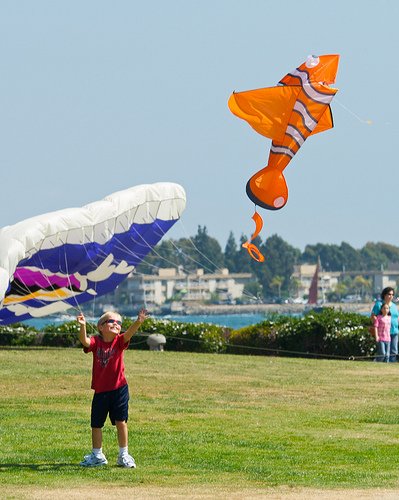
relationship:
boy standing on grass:
[76, 307, 151, 468] [0, 345, 398, 500]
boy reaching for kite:
[76, 307, 151, 468] [227, 53, 341, 262]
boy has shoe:
[76, 307, 151, 468] [78, 452, 109, 468]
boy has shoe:
[76, 307, 151, 468] [116, 452, 137, 469]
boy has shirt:
[76, 307, 151, 468] [83, 332, 130, 394]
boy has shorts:
[76, 307, 151, 468] [90, 384, 129, 428]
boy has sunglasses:
[76, 307, 151, 468] [100, 318, 123, 326]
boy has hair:
[76, 307, 151, 468] [97, 311, 122, 336]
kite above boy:
[227, 53, 341, 262] [76, 307, 151, 468]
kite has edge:
[0, 181, 187, 326] [0, 181, 187, 310]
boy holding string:
[76, 307, 151, 468] [57, 231, 101, 336]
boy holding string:
[76, 307, 151, 468] [85, 229, 261, 302]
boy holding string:
[76, 307, 151, 468] [119, 213, 259, 301]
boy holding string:
[76, 307, 151, 468] [142, 210, 259, 300]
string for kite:
[57, 231, 101, 336] [0, 181, 187, 326]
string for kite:
[85, 229, 261, 302] [0, 181, 187, 326]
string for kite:
[119, 213, 259, 301] [0, 181, 187, 326]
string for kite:
[142, 210, 259, 300] [0, 181, 187, 326]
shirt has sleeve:
[83, 332, 130, 394] [118, 332, 131, 350]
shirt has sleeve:
[83, 332, 130, 394] [83, 336, 96, 354]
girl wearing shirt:
[372, 302, 392, 362] [373, 314, 392, 342]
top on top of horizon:
[223, 231, 239, 275] [31, 223, 398, 319]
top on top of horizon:
[341, 241, 363, 270] [31, 223, 398, 319]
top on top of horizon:
[236, 232, 251, 273] [31, 223, 398, 319]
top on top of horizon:
[135, 239, 180, 273] [31, 223, 398, 319]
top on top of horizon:
[168, 236, 201, 268] [31, 223, 398, 319]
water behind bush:
[20, 311, 371, 330] [1, 322, 39, 347]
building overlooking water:
[85, 264, 251, 310] [20, 311, 371, 330]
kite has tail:
[227, 53, 341, 262] [241, 166, 289, 263]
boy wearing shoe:
[76, 307, 151, 468] [78, 452, 109, 468]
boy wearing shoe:
[76, 307, 151, 468] [116, 452, 137, 469]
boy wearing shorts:
[76, 307, 151, 468] [90, 384, 129, 428]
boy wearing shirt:
[76, 307, 151, 468] [83, 332, 130, 394]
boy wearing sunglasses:
[76, 307, 151, 468] [100, 318, 123, 326]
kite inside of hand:
[0, 181, 187, 326] [76, 312, 86, 326]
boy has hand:
[76, 307, 151, 468] [76, 312, 86, 326]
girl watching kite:
[372, 302, 392, 362] [227, 53, 341, 262]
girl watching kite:
[372, 302, 392, 362] [0, 181, 187, 326]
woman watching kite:
[370, 287, 398, 362] [227, 53, 341, 262]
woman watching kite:
[370, 287, 398, 362] [0, 181, 187, 326]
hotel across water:
[290, 263, 398, 304] [20, 311, 371, 330]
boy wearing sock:
[76, 307, 151, 468] [118, 445, 128, 456]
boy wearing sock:
[76, 307, 151, 468] [92, 447, 102, 457]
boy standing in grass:
[76, 307, 151, 468] [0, 345, 398, 500]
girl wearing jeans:
[372, 302, 392, 362] [377, 341, 391, 363]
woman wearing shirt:
[370, 287, 398, 362] [371, 299, 398, 335]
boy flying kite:
[76, 307, 151, 468] [0, 181, 187, 326]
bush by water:
[1, 322, 39, 347] [20, 311, 371, 330]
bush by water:
[40, 319, 96, 348] [20, 311, 371, 330]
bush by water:
[122, 314, 233, 354] [20, 311, 371, 330]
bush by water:
[226, 305, 377, 361] [20, 311, 371, 330]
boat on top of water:
[302, 255, 327, 317] [20, 311, 371, 330]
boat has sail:
[302, 255, 327, 317] [308, 254, 326, 307]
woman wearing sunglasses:
[370, 287, 398, 362] [387, 292, 394, 297]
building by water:
[85, 264, 251, 310] [20, 311, 371, 330]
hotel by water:
[290, 263, 398, 304] [20, 311, 371, 330]